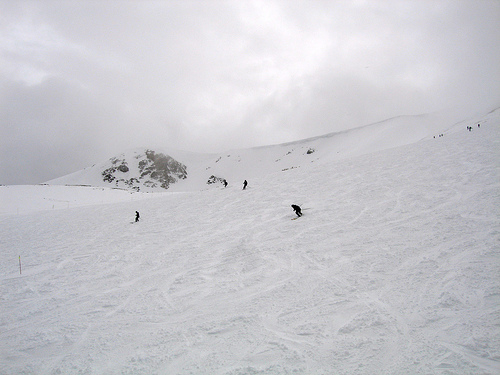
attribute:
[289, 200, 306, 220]
person — crouched, skiing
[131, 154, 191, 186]
mountain — snow-covered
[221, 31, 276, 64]
cloud — gray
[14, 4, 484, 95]
sky — cloudy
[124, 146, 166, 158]
top — rocky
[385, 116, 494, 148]
mountain top — snow-covered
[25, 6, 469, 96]
day — cloudy